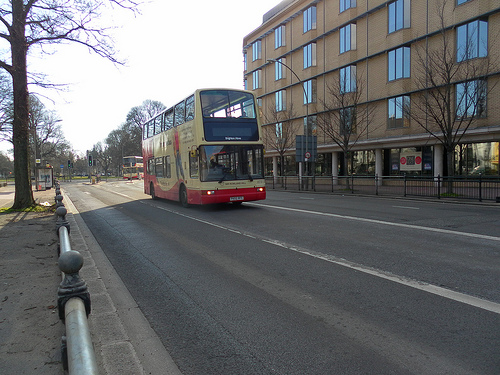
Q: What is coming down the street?
A: Bus.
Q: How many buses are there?
A: Two.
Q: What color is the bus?
A: Yellow and red.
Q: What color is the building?
A: Brown.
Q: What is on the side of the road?
A: Tree.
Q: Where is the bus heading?
A: Forward.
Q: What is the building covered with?
A: Windows.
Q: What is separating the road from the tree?
A: Fence.